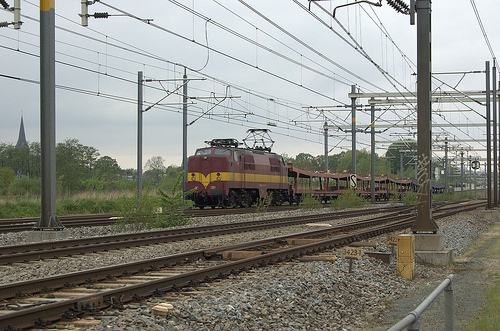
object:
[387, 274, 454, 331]
metal railing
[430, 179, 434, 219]
graffiti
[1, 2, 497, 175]
sky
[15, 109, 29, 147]
building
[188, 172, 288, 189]
stripe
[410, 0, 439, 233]
pole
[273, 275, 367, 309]
rocks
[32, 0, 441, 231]
poles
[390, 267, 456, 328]
silver rail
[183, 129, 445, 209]
train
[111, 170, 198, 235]
bush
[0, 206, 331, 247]
gravel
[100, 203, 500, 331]
ground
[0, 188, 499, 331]
tracks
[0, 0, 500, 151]
wires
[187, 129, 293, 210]
tennis shoe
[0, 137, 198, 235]
grass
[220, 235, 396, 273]
pieces